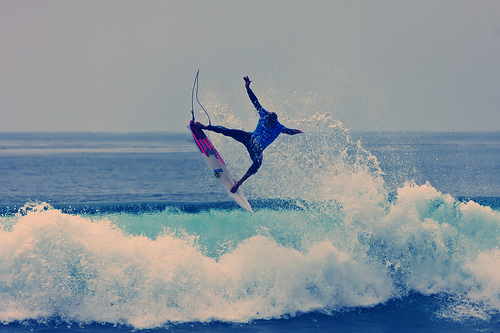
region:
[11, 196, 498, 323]
wave breaking in the ocean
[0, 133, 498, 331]
blue ocean waters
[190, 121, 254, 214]
pink and white surfboard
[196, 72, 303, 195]
surfer in a blue and black wetsuit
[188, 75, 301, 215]
man flying through the air on a surfboard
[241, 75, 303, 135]
the man's arms in the air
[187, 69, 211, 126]
the tether from the surfer's ankle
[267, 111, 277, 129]
the surfer's head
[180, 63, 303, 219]
surfer jumping off the top of the wave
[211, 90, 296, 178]
blue and black wetsuit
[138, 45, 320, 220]
person on a surf board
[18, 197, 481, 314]
white splash of water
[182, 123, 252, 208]
board surfer rides on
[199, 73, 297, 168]
surfer on the board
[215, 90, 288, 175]
wet suit on the surfer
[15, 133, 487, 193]
flat area of the water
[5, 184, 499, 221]
elevated area of water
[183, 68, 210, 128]
piece on end of surf board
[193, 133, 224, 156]
image on the board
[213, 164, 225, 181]
smaller image on the board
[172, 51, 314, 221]
the surfer in the air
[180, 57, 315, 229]
the man on the surfboard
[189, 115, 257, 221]
the surfboard in the air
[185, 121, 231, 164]
the pink designs on the white board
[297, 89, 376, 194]
water splashing into the air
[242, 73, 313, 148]
the arms of the surfer stretched out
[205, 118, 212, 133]
the strap on the mans ankle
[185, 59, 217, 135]
the strink for the strap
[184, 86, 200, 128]
the chord connected to the base of the board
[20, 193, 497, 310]
the waves crashing under the surfer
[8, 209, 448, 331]
a large wave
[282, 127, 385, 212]
splashes coming from the water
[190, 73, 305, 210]
a person on a surf board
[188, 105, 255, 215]
a white and red surf board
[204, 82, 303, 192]
a person wearing a blue shirt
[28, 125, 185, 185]
the water in the distance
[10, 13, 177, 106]
a clear grey sky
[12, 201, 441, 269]
a large wave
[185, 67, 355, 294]
a man jumping off the water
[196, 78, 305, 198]
a surfer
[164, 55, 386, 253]
this person is catching air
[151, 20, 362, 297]
this person is surfing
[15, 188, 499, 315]
the wave is crashing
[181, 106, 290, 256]
the person's board is white, blue, and pink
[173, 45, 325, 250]
the person is wearing a blue rash guard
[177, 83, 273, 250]
the surfboard has neon pink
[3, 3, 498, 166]
the sky is grey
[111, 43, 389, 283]
this person is hoping to keep balanced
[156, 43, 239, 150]
the person is attached to their board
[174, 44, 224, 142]
this cord keeps the surfer connected to their board